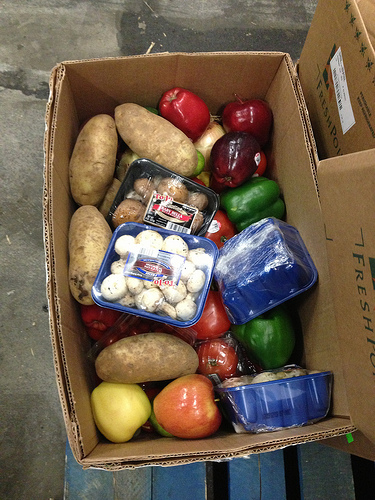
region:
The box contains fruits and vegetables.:
[42, 75, 299, 350]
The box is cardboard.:
[292, 31, 368, 200]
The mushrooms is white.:
[100, 215, 209, 318]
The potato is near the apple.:
[93, 344, 204, 392]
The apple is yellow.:
[87, 384, 155, 439]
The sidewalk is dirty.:
[91, 5, 259, 68]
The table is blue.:
[63, 457, 361, 497]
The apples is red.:
[211, 132, 264, 181]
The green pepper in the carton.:
[222, 181, 291, 230]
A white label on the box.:
[302, 48, 364, 139]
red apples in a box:
[154, 76, 277, 188]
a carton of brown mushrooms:
[113, 158, 223, 246]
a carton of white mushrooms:
[86, 219, 240, 330]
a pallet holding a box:
[48, 434, 372, 494]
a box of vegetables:
[26, 45, 369, 465]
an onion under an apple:
[189, 105, 238, 165]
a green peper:
[234, 304, 307, 369]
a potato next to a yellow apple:
[78, 322, 198, 387]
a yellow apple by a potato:
[86, 381, 168, 455]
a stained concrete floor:
[51, 1, 310, 62]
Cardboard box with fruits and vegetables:
[55, 61, 355, 451]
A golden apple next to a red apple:
[90, 375, 219, 442]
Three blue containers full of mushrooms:
[91, 219, 332, 423]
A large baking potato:
[95, 331, 192, 378]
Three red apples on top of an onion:
[155, 90, 270, 186]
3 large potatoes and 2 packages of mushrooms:
[63, 108, 209, 308]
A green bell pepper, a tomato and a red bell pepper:
[172, 280, 300, 371]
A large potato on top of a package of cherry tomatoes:
[87, 300, 194, 378]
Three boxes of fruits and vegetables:
[35, 12, 368, 492]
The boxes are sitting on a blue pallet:
[1, 160, 369, 490]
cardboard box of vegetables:
[33, 47, 359, 474]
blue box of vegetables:
[85, 220, 224, 331]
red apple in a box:
[152, 370, 227, 442]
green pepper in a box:
[230, 318, 309, 369]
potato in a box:
[65, 108, 122, 204]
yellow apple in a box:
[87, 382, 153, 448]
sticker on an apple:
[249, 149, 264, 172]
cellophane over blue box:
[219, 244, 277, 271]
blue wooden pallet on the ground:
[45, 473, 373, 497]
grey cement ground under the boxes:
[4, 65, 46, 491]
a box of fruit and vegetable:
[41, 23, 373, 303]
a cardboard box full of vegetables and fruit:
[32, 18, 364, 429]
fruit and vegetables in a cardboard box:
[31, 55, 359, 457]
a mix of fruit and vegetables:
[55, 66, 345, 440]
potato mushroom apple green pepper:
[85, 65, 284, 221]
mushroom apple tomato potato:
[73, 216, 300, 424]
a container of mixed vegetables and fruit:
[25, 33, 340, 366]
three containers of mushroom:
[91, 130, 346, 458]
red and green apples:
[67, 342, 244, 445]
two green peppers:
[193, 167, 316, 379]